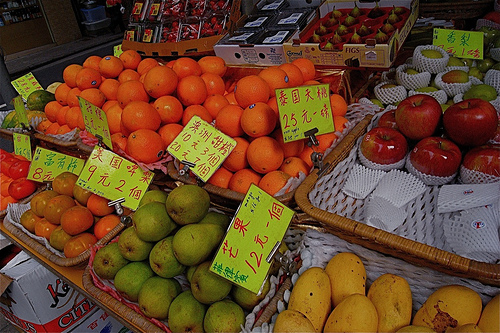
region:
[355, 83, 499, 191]
Red apples wrapped in white casings.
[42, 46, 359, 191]
Pile of oranges in the center of table.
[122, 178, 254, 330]
Pears below the pile of oranges on the table.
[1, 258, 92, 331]
Cardboard box below the table holding the fruits.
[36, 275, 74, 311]
Letter K on the cardboard box.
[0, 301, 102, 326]
Orange stripe on cardboard box.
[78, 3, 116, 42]
Bins stacked on top of each other in the back ground.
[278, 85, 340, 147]
Yellow sign with red lettering with the number 25 on it.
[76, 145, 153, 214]
Yellow sign with red writing with the numbers 9 and 2 on it.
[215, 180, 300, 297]
Yellow sign with red writing with the number 12 on it.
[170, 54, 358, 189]
Oranges in wicker basket.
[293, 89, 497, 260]
Red apples in wicker basket.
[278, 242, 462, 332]
Mangoes in wicker basket.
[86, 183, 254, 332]
Green pears in wicker basket.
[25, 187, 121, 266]
Tangerines in wicker basket.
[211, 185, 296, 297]
Yellow price signs with red and green writing.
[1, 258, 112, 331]
White and orange card board box.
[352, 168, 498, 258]
White textured paper holding apples.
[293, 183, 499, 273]
A brown wicker basket.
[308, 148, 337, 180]
Metal clip holding baskets together.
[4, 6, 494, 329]
A display of fresh fruit.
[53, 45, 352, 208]
A display of oranges.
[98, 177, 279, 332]
Pears displayed in a basket.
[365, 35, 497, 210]
Apples displayed in white foam holders.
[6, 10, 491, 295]
The food labels are written in an Asian language.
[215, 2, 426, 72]
Crates in background have fruite.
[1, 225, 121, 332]
Box underneath the shelf.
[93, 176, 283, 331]
Several green pairs in a basket.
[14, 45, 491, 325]
Wicker baskets holding fruit.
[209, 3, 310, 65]
A white crate holding fruit.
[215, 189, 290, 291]
yellow price sign with oriental lettering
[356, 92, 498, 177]
shiny red apples for sale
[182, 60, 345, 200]
oranges stacked in basket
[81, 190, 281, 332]
green pears laying on their sides in a basket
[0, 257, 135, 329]
white cardboard box with orange and black lettering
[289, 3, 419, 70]
flat crate of pears nestled in individual cups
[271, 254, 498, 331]
oblong yellow fruit in basket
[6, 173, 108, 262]
small basket of tangerines at front of display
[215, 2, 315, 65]
plastic tubs of berries in a flat crate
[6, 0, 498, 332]
fruit stand in an outdoor market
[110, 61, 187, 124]
stack of oranges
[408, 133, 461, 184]
one red apple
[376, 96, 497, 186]
A stack of red apples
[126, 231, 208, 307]
A stack of pears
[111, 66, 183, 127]
7 oranges in a stack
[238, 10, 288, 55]
box of blueberries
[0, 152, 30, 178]
a stack of tomatoes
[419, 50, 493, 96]
Green apples stacked on top of each other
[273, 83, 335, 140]
A sign stating price for oranges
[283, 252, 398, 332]
a basket of yellow fruit